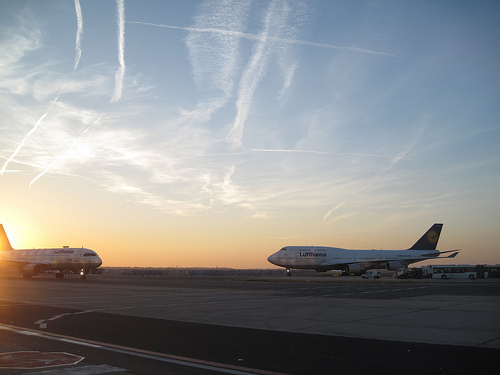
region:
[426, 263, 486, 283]
A shuttle bus behind an airplane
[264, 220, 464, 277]
An airplane next to a shuttle bus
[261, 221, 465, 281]
Airliner sitting idle next to a bus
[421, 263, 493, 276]
A bus next to an airliner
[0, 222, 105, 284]
An airplane nearer toward the sun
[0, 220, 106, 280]
An airplane obstructing a sunset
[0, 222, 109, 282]
An airplane obstructing a sun rise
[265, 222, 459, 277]
large white airplane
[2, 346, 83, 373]
painted red and white symbol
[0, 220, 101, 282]
white airplane on a runway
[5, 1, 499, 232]
blue sky with jet smoke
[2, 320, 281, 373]
orange and white stripe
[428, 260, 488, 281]
large white transit bus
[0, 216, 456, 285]
two airplanes at a runway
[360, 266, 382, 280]
white airport vehicle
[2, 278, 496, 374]
grey and black cement runway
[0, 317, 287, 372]
painting on black cement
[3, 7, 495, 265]
blue sky turning yellow at horizon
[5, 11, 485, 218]
streaky and puffy clouds across sky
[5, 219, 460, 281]
airplanes facing towards each other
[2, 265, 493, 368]
paved ground at airport with stripes and symbols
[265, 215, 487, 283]
airport service vehicles in front of plane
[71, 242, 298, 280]
small white lights glowing under front of planes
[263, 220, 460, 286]
dark tail on light-colored plane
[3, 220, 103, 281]
bright light of low sun behind plane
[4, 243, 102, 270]
muted gray and yellow pattern across plane body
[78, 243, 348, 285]
row of trees between planes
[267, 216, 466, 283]
plane on the runway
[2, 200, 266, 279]
sky is orange and blue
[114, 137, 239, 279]
sky is orange and blue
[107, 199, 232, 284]
sky is orange and blue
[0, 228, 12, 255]
The tail of the plane on the left.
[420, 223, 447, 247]
The tail of the plane on the right.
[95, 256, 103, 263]
The nose of the plane on the left.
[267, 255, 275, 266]
The nose of the plane on the right.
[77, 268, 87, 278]
The front wheels of the plane on the left.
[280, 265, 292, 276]
The front wheels of the plane on the right.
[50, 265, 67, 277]
The back wheels of the plane on the left.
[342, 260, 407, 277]
The side engines of the plane on the right.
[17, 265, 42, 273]
The engine on the left wing of the plane on the left.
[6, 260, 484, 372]
The runway the planes are located.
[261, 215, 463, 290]
airplane in an airport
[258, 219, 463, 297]
airplane is color white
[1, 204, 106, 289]
the sun behind an airplane